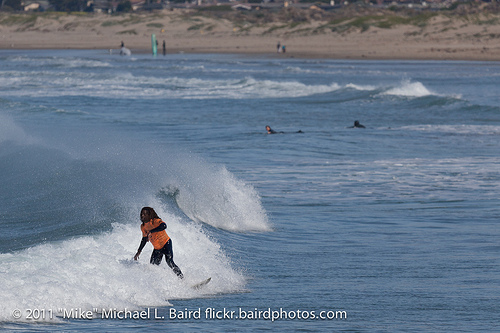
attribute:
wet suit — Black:
[150, 238, 184, 281]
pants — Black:
[150, 240, 190, 290]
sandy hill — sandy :
[138, 0, 478, 51]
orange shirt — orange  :
[138, 223, 184, 256]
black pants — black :
[155, 248, 191, 284]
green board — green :
[150, 41, 162, 53]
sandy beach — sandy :
[3, 21, 485, 65]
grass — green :
[247, 0, 249, 3]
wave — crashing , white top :
[202, 179, 267, 229]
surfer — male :
[95, 110, 375, 295]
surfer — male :
[95, 94, 359, 298]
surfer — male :
[112, 181, 205, 293]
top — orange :
[140, 214, 174, 243]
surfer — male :
[346, 110, 386, 143]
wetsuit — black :
[354, 120, 363, 145]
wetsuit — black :
[351, 109, 363, 132]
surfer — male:
[337, 105, 375, 144]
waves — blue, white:
[53, 260, 168, 317]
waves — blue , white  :
[26, 279, 188, 306]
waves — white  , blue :
[12, 142, 133, 245]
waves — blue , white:
[24, 261, 136, 326]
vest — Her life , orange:
[144, 217, 179, 263]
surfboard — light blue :
[89, 256, 201, 290]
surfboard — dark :
[113, 253, 226, 305]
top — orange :
[144, 211, 175, 251]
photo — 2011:
[2, 4, 484, 311]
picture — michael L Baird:
[10, 2, 479, 312]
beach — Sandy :
[70, 23, 450, 66]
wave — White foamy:
[82, 123, 296, 194]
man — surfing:
[130, 197, 188, 282]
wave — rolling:
[293, 77, 458, 109]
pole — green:
[148, 28, 160, 57]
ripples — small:
[313, 159, 456, 208]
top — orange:
[141, 223, 171, 248]